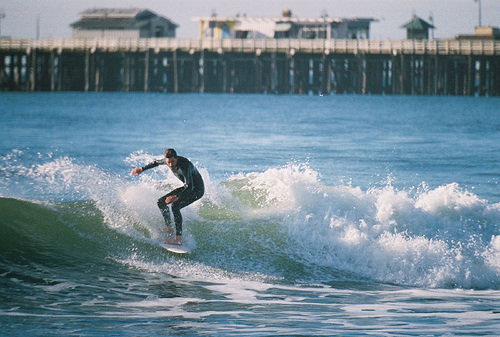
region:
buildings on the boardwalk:
[66, 0, 498, 50]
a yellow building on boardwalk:
[195, 8, 269, 44]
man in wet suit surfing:
[125, 142, 213, 256]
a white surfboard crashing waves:
[145, 232, 191, 264]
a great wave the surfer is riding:
[6, 188, 240, 276]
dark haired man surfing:
[128, 145, 194, 210]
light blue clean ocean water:
[45, 90, 398, 136]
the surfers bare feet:
[149, 219, 189, 246]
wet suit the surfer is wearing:
[145, 152, 202, 230]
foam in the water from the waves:
[220, 270, 380, 330]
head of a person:
[153, 137, 184, 170]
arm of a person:
[137, 153, 174, 169]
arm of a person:
[176, 170, 203, 195]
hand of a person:
[128, 156, 141, 176]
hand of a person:
[156, 182, 174, 209]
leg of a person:
[152, 188, 182, 229]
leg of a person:
[163, 200, 196, 230]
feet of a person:
[148, 222, 170, 234]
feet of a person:
[158, 233, 198, 248]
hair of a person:
[162, 139, 187, 154]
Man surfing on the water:
[149, 133, 219, 258]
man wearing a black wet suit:
[123, 133, 209, 236]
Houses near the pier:
[62, 4, 452, 45]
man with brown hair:
[153, 146, 175, 166]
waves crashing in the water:
[231, 182, 462, 273]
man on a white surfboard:
[117, 140, 204, 275]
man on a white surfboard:
[132, 186, 198, 251]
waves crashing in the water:
[323, 231, 474, 298]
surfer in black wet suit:
[132, 146, 207, 236]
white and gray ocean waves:
[265, 160, 320, 212]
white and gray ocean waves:
[312, 156, 357, 221]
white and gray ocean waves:
[312, 216, 357, 266]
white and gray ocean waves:
[16, 145, 66, 191]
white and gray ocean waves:
[230, 102, 277, 147]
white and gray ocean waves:
[45, 96, 111, 153]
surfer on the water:
[126, 143, 217, 260]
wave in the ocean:
[8, 186, 114, 278]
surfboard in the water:
[161, 234, 192, 256]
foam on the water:
[211, 279, 258, 309]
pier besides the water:
[8, 34, 485, 115]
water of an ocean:
[266, 93, 425, 149]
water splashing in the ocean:
[283, 153, 450, 250]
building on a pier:
[70, 2, 172, 42]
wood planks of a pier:
[406, 58, 473, 106]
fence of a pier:
[190, 14, 349, 44]